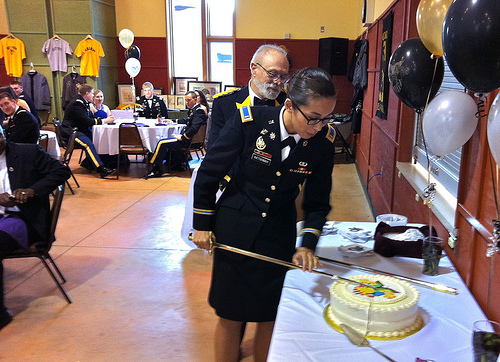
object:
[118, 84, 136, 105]
photos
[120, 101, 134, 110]
documents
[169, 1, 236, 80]
window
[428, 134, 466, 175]
ground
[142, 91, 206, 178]
men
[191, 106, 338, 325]
uniform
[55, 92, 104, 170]
uniform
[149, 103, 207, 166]
uniform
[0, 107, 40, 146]
uniform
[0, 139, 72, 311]
uniform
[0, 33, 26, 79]
jersey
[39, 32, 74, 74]
jersey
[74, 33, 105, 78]
jersey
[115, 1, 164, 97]
wall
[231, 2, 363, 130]
wall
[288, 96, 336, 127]
glasses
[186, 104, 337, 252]
jacket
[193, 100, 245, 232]
sleeve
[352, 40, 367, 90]
black backpack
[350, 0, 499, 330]
wall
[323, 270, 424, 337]
cake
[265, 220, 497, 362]
table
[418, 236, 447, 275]
cup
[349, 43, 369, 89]
shirt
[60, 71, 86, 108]
shirt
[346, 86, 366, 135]
shirt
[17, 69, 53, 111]
shirt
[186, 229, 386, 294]
knife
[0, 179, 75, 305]
chair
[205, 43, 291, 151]
man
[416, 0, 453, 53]
ballon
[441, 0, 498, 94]
ballon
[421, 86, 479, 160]
ballon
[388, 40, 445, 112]
ballon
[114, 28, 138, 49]
ballon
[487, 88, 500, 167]
balloon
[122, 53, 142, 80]
balloon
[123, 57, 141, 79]
balloon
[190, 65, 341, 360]
officer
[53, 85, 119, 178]
people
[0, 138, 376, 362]
floor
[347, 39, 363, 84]
shirts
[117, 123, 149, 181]
chair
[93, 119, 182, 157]
tablecloth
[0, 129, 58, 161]
tables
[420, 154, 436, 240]
balloon strings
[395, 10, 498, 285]
centerpiece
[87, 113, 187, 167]
table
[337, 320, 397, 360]
cake server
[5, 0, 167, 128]
wall